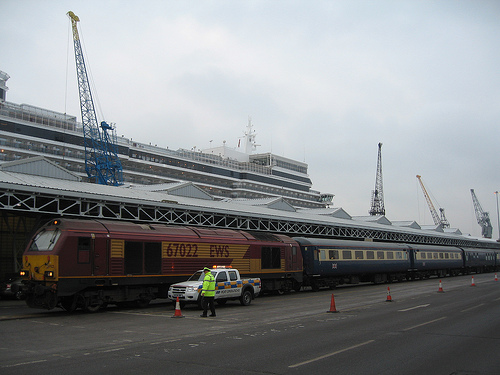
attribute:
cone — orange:
[325, 292, 340, 312]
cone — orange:
[323, 287, 343, 313]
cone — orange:
[321, 287, 338, 310]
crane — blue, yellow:
[60, 5, 132, 183]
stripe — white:
[171, 300, 182, 310]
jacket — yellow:
[200, 271, 220, 297]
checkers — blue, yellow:
[211, 276, 261, 288]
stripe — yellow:
[314, 243, 463, 263]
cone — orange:
[380, 280, 391, 301]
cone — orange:
[382, 279, 399, 302]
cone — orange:
[381, 284, 393, 304]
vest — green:
[196, 271, 218, 299]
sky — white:
[4, 2, 484, 235]